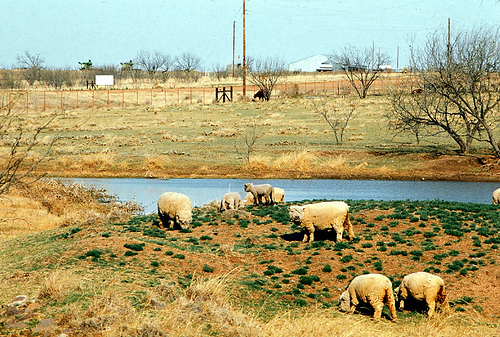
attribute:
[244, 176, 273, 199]
sheep — baby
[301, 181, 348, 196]
river — flowing, blue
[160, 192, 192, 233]
sheep — grazing, feeding, eating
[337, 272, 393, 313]
sheep — grazing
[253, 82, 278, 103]
cow — grazing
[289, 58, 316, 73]
building — big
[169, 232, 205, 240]
grass — brown, green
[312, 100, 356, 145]
tree — dry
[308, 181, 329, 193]
water — calm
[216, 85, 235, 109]
fence — wooden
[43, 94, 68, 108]
fence — orange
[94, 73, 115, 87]
house — white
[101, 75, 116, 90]
shed — tiny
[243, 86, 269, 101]
animal — black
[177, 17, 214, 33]
sky — blue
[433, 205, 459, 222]
plant — green